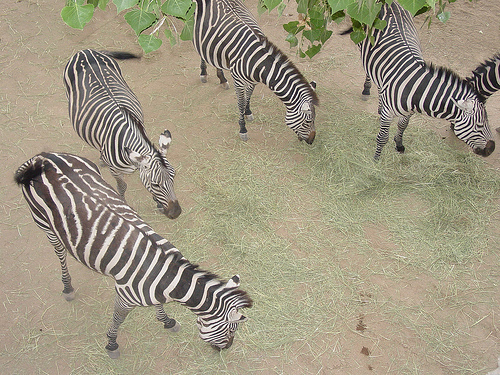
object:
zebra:
[62, 47, 183, 220]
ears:
[123, 145, 148, 166]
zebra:
[193, 0, 321, 145]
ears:
[301, 101, 312, 114]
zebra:
[361, 0, 496, 164]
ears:
[451, 97, 473, 113]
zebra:
[15, 152, 255, 360]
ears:
[228, 306, 249, 323]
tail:
[14, 160, 45, 187]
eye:
[152, 184, 160, 188]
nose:
[162, 199, 181, 220]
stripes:
[89, 63, 123, 130]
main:
[257, 33, 321, 107]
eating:
[231, 328, 296, 356]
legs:
[374, 114, 395, 162]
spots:
[355, 314, 368, 334]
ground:
[0, 0, 500, 375]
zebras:
[463, 51, 499, 107]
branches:
[59, 0, 455, 60]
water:
[360, 345, 372, 356]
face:
[140, 152, 183, 219]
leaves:
[60, 2, 96, 31]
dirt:
[371, 268, 440, 302]